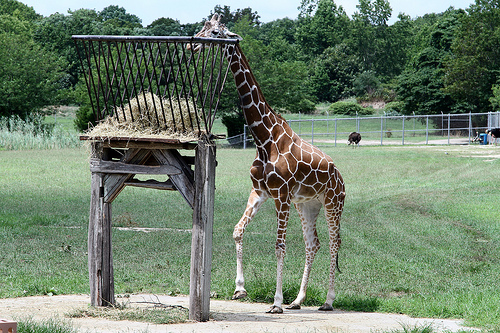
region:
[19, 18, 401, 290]
picture taken outside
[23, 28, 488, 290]
picture taken during the day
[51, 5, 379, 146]
a giraffe is feeding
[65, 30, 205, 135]
the food is hay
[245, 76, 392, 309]
the giraffe is tall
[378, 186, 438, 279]
the grass is mowed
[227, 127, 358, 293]
the giraffe's legs are long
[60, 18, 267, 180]
the container holds food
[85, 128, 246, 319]
the legs are made of wood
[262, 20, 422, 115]
the tall trees in the background are green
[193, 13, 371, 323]
the giraffe is reacing the hay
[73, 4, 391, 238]
the giraffe is reacing the hay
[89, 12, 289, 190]
the giraffe is reacing the hay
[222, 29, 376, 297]
giraffe's fur is brown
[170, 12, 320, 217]
giraffe's fur is brown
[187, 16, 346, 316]
The giraffe is standing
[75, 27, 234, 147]
The feeder is black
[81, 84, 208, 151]
The hay is brown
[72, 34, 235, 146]
Hay in the feeder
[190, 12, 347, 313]
The giraffe is spotted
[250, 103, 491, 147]
Grey chain link fence behind the giraffe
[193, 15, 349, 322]
The giraffe is on dirt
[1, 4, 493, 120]
Trees behind the fence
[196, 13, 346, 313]
The giraffe is brown and white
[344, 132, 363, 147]
The ostrich is pecking the ground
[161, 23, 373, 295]
giraffe eats out of dispenser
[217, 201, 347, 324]
giraffe has white legs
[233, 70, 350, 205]
brown and white spots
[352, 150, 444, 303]
green grass around giraffe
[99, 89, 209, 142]
yellow hay in cage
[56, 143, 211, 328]
wooden support for cage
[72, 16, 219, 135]
black bars on cage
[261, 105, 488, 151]
grey fence behind giraffe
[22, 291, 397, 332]
dead ground near giraffe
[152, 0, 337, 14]
blue sky in background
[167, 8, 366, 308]
a giraffe eating from a feeder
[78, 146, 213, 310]
wooden posts of the feeder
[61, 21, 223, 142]
a black metal feeder filled with hay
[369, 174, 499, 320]
green grass of the field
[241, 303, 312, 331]
tan dirt of the ground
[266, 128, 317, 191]
brown spots of the giraffe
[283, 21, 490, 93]
trees growing outside the enclosure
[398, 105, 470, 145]
grey metal fence surrounding the enclosure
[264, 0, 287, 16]
clear blue skies over the field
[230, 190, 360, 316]
long legs of the giraffe